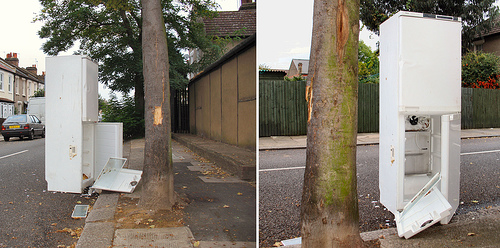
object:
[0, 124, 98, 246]
road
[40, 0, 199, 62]
branch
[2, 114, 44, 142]
car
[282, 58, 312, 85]
house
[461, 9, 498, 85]
house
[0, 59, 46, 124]
house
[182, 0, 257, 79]
house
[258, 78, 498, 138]
fence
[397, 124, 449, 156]
ground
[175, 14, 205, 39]
leaf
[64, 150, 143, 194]
pieces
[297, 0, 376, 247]
tree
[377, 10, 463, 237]
fridge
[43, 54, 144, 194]
fridge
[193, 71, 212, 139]
door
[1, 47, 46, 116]
building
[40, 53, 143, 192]
refrigerator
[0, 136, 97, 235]
street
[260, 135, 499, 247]
street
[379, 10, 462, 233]
refrigerator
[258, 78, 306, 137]
fencing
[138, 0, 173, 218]
trunk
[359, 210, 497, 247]
curb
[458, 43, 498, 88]
bush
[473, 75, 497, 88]
roses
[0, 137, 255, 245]
ground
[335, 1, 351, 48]
hole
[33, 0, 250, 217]
tree